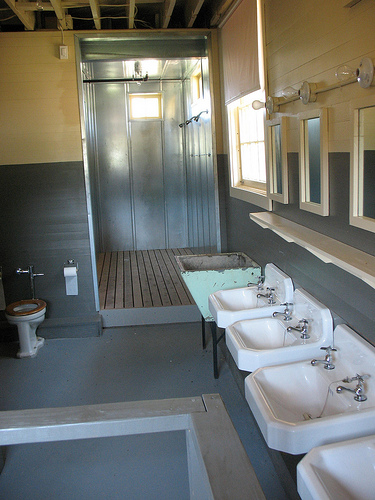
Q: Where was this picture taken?
A: Bathroom.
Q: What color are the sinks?
A: White.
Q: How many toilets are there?
A: One.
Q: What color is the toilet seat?
A: Brown.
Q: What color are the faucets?
A: Silver.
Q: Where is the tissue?
A: On the wall.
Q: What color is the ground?
A: Grey.